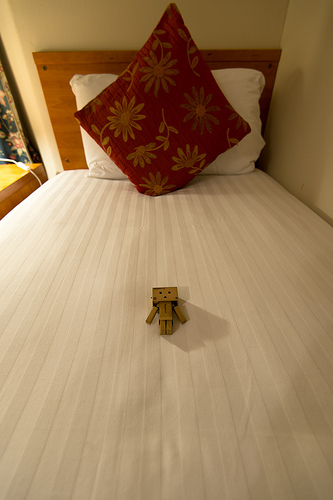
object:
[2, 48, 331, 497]
bed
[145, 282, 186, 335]
doll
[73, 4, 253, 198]
pillow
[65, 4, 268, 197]
two pillows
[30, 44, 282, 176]
head board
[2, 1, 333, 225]
wall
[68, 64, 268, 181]
pillow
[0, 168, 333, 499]
bed spread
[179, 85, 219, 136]
flower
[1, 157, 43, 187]
cord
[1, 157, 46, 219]
table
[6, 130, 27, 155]
floral print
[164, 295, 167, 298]
nose